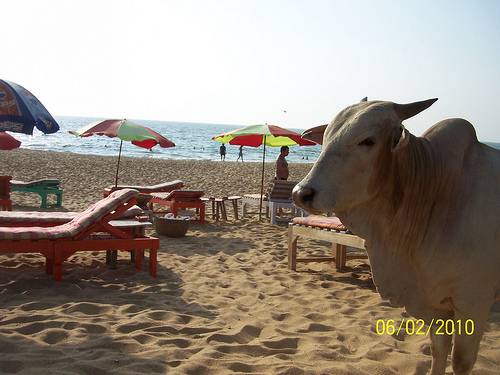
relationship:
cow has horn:
[288, 97, 500, 375] [397, 97, 437, 119]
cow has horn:
[288, 97, 500, 375] [298, 120, 328, 144]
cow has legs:
[267, 104, 498, 372] [428, 323, 484, 373]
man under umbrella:
[273, 142, 295, 182] [210, 120, 317, 152]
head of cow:
[297, 87, 408, 231] [293, 96, 476, 337]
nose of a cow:
[292, 185, 318, 214] [288, 97, 500, 375]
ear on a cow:
[387, 117, 414, 157] [288, 97, 500, 375]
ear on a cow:
[295, 117, 329, 154] [288, 97, 500, 375]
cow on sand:
[288, 97, 500, 375] [2, 145, 497, 373]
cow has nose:
[288, 97, 500, 375] [290, 172, 326, 226]